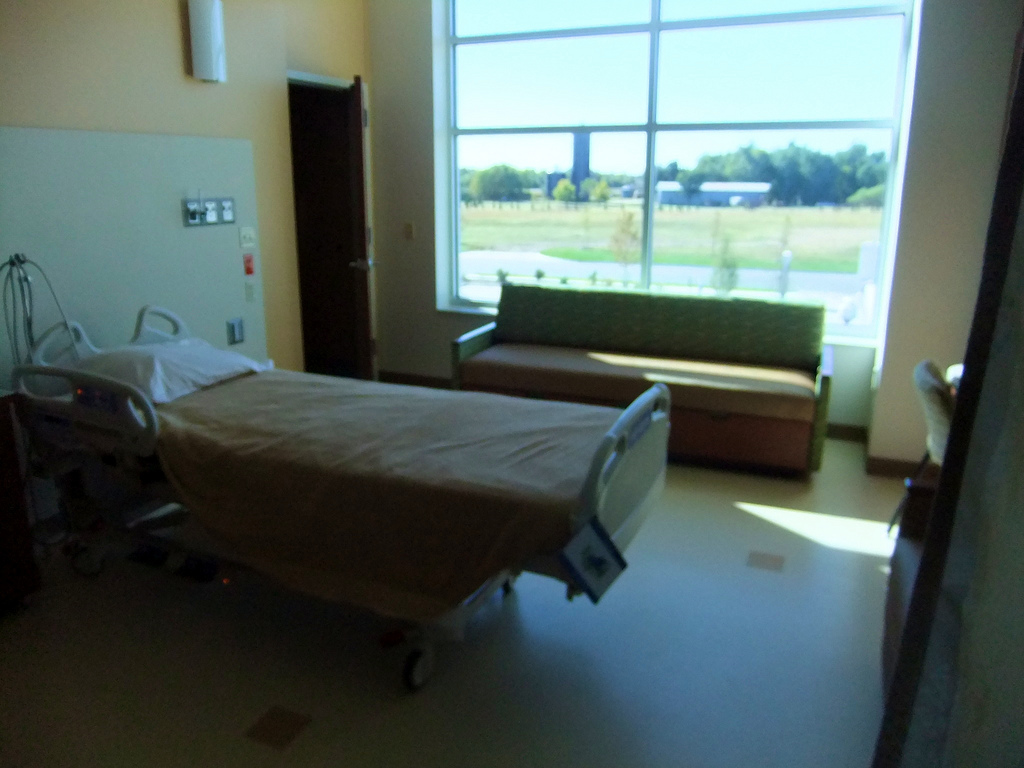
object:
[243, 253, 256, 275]
switch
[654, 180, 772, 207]
barn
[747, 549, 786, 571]
tile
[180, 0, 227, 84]
light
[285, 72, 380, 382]
door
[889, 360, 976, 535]
chair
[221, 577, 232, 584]
dot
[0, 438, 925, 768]
floor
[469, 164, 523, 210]
tree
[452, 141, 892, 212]
woods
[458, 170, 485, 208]
tree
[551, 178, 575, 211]
tree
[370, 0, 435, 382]
outside wall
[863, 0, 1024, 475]
outside wall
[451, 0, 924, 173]
sky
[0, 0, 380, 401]
wall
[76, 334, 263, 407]
pillow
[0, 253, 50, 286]
gadget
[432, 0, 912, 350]
panel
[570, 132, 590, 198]
silo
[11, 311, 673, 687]
bed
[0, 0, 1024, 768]
building